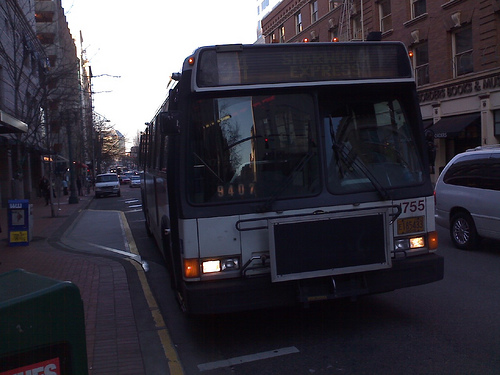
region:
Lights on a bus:
[176, 229, 233, 295]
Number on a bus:
[389, 179, 438, 219]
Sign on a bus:
[187, 36, 430, 96]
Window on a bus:
[187, 89, 332, 200]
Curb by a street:
[54, 211, 174, 334]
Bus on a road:
[116, 34, 468, 320]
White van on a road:
[427, 133, 497, 233]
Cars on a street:
[93, 142, 144, 221]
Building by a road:
[257, 1, 497, 138]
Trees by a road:
[60, 24, 142, 205]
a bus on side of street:
[123, 25, 452, 341]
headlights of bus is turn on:
[175, 222, 442, 284]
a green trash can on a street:
[0, 248, 104, 372]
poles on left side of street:
[76, 30, 124, 199]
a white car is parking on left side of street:
[87, 163, 123, 205]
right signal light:
[421, 220, 446, 255]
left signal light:
[179, 256, 199, 280]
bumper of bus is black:
[170, 247, 450, 324]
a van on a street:
[421, 136, 496, 258]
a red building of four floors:
[253, 0, 497, 47]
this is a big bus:
[166, 7, 444, 295]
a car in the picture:
[90, 155, 125, 196]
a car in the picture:
[441, 160, 498, 247]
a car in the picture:
[127, 170, 158, 193]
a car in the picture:
[116, 167, 136, 186]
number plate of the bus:
[391, 216, 436, 241]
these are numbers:
[398, 197, 432, 219]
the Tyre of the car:
[445, 207, 477, 246]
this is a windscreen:
[341, 144, 401, 213]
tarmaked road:
[328, 303, 433, 361]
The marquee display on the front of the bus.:
[201, 50, 401, 82]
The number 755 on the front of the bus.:
[399, 195, 426, 215]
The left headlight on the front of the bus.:
[203, 252, 223, 274]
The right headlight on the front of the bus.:
[407, 235, 425, 252]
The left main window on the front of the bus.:
[189, 99, 321, 196]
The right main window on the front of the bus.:
[317, 92, 424, 189]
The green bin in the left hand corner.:
[2, 267, 104, 373]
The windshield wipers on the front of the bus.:
[230, 127, 403, 211]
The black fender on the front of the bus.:
[185, 266, 452, 303]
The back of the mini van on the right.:
[430, 138, 497, 250]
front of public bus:
[130, 37, 441, 320]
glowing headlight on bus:
[189, 249, 229, 281]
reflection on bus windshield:
[210, 96, 283, 189]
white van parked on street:
[85, 170, 123, 202]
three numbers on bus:
[395, 196, 432, 221]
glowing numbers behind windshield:
[209, 176, 261, 208]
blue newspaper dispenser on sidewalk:
[6, 196, 38, 252]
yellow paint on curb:
[149, 301, 185, 373]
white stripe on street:
[193, 340, 302, 372]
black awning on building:
[427, 103, 487, 144]